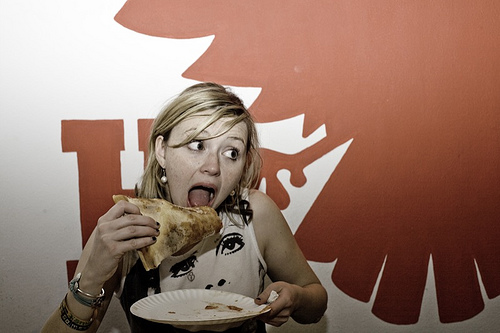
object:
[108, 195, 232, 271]
pizza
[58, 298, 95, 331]
bracelets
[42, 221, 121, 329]
arm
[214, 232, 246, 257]
eye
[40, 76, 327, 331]
lady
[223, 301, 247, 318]
sauce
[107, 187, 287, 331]
shirt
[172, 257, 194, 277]
eye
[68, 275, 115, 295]
wrist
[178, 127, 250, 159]
eyes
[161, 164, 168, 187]
earring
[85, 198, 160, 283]
hand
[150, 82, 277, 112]
blonde hair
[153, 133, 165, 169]
ear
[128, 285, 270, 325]
paper plate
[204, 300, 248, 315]
sauce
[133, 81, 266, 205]
hair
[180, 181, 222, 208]
mouth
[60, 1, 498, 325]
symbol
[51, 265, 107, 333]
bracelets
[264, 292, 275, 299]
napkin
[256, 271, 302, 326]
hand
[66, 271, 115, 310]
bracelets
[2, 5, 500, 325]
wall